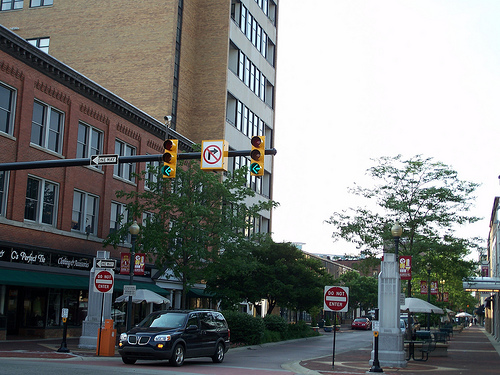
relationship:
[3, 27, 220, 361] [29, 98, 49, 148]
building has window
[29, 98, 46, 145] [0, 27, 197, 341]
glass window on building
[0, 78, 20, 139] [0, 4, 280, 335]
window on building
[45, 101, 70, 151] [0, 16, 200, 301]
glass window on building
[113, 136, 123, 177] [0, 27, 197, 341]
window on building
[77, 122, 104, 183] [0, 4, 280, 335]
window on building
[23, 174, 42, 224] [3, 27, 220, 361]
window on building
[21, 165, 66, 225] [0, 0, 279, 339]
window on brown building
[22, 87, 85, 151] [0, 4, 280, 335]
window on building